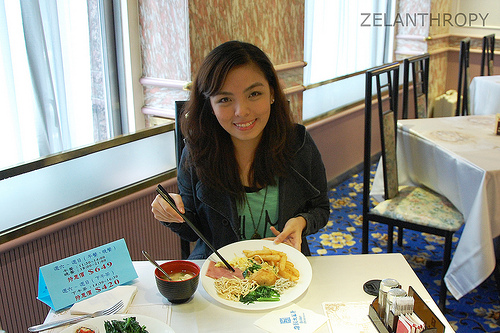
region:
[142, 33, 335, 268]
Woman holding a plate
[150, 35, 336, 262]
Woman holding chop sticks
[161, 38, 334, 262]
Woman sitting in a chair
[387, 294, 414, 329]
Box full of toothpicks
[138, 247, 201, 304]
Bowl with spoon inside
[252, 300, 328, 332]
Napkin laying flat on a table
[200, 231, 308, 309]
Plate full of Asian food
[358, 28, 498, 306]
Tables with chairs pulled up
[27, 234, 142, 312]
Blue sign with Asian writing on it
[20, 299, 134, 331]
Silver fork on a table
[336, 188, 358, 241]
blue colourd floor with flowers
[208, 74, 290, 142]
a girl is smilling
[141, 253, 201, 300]
a cup with a drink and a spoon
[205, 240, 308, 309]
a white plate filled with food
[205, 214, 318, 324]
the girl holding a plate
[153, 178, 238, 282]
her right hand is holding a chopstick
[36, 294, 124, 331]
a fork is placed on a towel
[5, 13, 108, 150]
the window is closed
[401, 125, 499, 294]
a white tablecloth spread on the tasble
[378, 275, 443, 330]
spices placed on the table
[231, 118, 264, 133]
the girl is smiling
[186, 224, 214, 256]
the chopsticks are black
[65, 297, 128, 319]
the fork is silver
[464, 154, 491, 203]
the tablecloth is white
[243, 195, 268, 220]
the shirt is green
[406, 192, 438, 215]
the chair cusion has flowers on it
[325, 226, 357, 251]
the flower is yellow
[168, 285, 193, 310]
the bowl is sitting on the table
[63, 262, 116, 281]
the number is red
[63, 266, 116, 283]
the sign is blue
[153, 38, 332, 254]
a woman sitting at a table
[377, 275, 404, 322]
a pepper and slat shaker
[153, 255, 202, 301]
a black and red bowl of soup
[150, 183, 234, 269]
a woman holding black chopsticks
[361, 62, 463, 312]
a black chair with a stuffed colorful cushion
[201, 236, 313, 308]
a plate of meat, pasta and veggies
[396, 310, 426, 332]
packages of sugar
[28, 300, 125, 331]
a stainless steel fork on a table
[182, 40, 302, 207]
a woman with long brown hair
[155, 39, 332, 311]
a woman eating in a restaurant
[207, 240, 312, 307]
A plate full of food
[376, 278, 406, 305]
Spice in the tray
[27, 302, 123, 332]
A fork on the table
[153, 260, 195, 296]
A small cup of soup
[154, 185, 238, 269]
Chopsticks in her hand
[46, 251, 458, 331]
A white table next to a window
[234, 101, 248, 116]
The nose of the woman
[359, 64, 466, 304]
A chair at a nearby table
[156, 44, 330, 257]
A woman eating at the table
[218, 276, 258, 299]
Noodles on the white plate